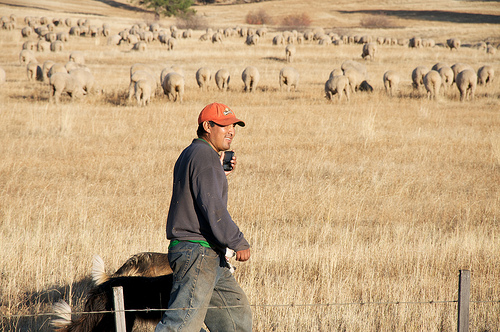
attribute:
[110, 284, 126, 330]
post — slanted, fence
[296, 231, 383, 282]
stalks — tan, green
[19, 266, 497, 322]
fence — wooden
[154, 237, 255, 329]
jeans — grey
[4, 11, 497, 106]
sheep — eating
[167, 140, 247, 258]
sweatshirt — black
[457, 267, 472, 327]
post — wooden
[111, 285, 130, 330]
post — wooden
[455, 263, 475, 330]
post — straight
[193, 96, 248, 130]
cap — red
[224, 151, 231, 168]
cell phone — black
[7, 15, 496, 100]
herd — sheep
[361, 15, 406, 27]
tree — bush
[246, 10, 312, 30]
tree — bush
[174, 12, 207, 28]
tree — bush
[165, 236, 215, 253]
undershirt — green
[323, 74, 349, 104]
elephants — large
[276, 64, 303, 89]
elephants — large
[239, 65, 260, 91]
elephants — large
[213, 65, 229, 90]
elephants — large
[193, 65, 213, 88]
elephants — large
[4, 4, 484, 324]
hay — tall, brown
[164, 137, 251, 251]
sweater — blue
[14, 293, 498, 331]
wire — silver, barbed